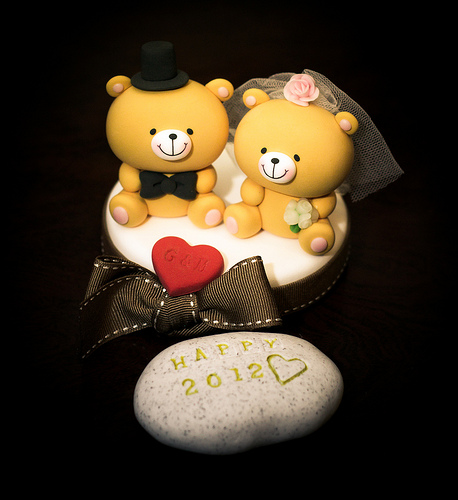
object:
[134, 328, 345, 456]
stone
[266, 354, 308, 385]
heart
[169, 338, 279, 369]
happy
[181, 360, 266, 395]
2012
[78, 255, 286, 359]
ribbon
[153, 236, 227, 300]
heart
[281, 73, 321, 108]
rose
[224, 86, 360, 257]
bear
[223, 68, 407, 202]
veil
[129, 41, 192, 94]
top hat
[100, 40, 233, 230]
bear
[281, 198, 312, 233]
flower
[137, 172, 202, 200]
bow tie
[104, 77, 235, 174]
head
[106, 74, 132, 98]
ear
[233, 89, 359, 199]
head